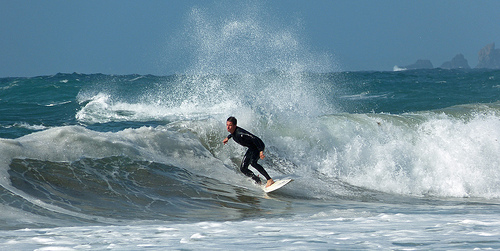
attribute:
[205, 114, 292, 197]
man — white, surfing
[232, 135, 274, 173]
suit — black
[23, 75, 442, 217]
water — blue, white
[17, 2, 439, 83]
sky — blue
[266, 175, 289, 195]
board — white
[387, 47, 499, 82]
rocks — grey